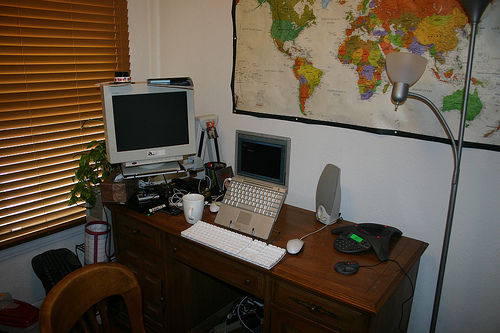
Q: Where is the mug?
A: On the desk.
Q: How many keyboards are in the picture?
A: Two.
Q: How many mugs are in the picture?
A: One.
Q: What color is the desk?
A: Brown.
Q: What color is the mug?
A: White.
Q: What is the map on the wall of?
A: The world.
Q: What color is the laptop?
A: Silver.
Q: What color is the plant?
A: Green.